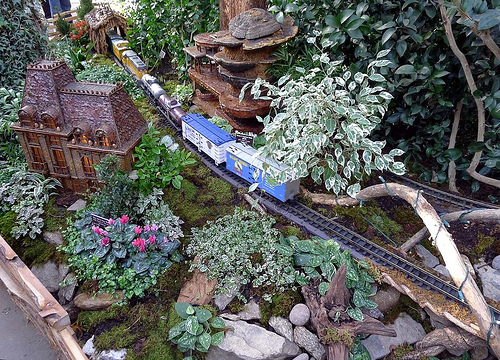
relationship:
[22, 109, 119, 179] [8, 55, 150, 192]
windows on side of building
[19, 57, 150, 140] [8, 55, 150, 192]
roof on top of building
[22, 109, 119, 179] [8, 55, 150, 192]
windows are on side of building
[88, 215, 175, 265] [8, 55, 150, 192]
flowers are near building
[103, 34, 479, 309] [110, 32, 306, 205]
train tracks are in front of train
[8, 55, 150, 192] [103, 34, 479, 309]
building besides train tracks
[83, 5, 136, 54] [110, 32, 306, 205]
tunnel for train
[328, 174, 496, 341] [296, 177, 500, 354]
lights are wrapped around branch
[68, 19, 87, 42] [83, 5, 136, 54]
flowers are by tunnel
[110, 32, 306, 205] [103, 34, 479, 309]
train on train tracks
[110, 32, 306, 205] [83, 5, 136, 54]
train passing through a tunnel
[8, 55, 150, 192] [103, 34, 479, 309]
building near train tracks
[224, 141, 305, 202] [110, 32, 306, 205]
train car on train